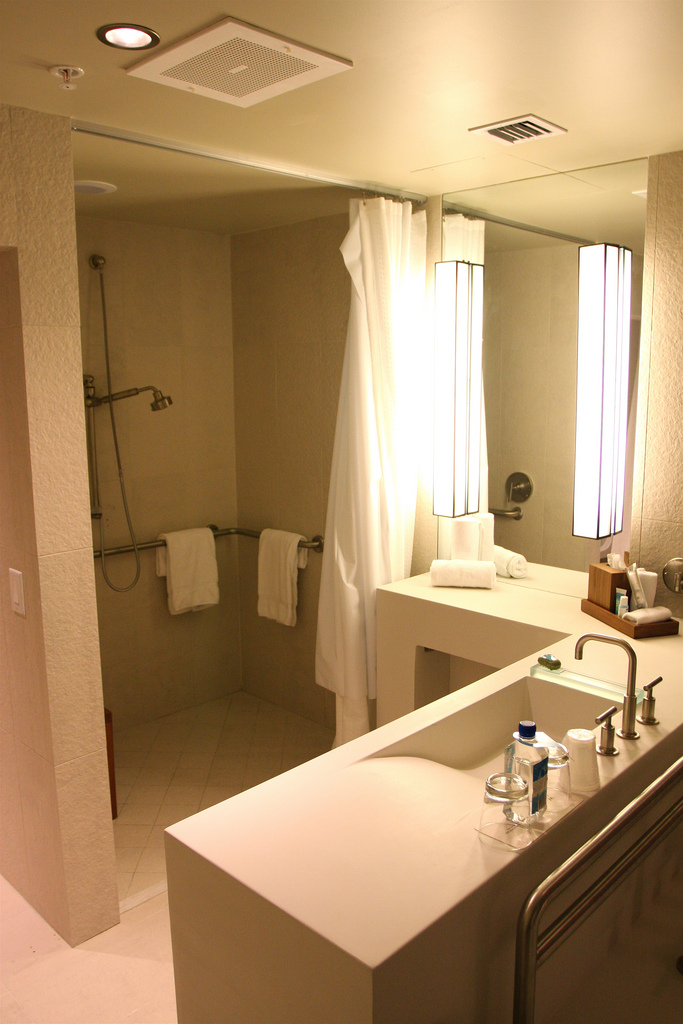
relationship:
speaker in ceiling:
[120, 14, 354, 116] [3, 5, 681, 201]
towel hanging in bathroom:
[156, 530, 218, 615] [0, 4, 680, 1021]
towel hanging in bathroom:
[257, 529, 309, 628] [0, 4, 680, 1021]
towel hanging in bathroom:
[431, 559, 495, 588] [0, 4, 680, 1021]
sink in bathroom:
[367, 661, 650, 826] [0, 4, 680, 1021]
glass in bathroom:
[489, 774, 529, 854] [0, 4, 680, 1021]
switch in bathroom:
[8, 566, 26, 622] [0, 4, 680, 1021]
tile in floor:
[228, 688, 257, 717] [0, 678, 356, 1020]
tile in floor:
[257, 703, 291, 728] [0, 678, 356, 1020]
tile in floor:
[273, 707, 311, 739] [0, 678, 356, 1020]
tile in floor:
[243, 741, 281, 774] [0, 678, 356, 1020]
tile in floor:
[178, 721, 220, 757] [0, 678, 356, 1020]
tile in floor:
[140, 715, 180, 751] [0, 678, 356, 1020]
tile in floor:
[158, 775, 210, 815] [0, 678, 356, 1020]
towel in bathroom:
[156, 530, 218, 615] [0, 4, 680, 1021]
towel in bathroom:
[257, 530, 313, 633] [0, 4, 680, 1021]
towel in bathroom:
[431, 559, 495, 588] [0, 4, 680, 1021]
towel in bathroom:
[490, 541, 530, 581] [0, 4, 680, 1021]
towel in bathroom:
[451, 518, 479, 561] [0, 4, 680, 1021]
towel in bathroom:
[473, 512, 492, 560] [0, 4, 680, 1021]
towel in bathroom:
[621, 598, 669, 622] [0, 4, 680, 1021]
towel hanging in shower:
[158, 476, 238, 595] [46, 171, 388, 882]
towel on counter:
[257, 529, 309, 628] [385, 531, 606, 658]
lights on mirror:
[641, 147, 659, 228] [406, 146, 656, 557]